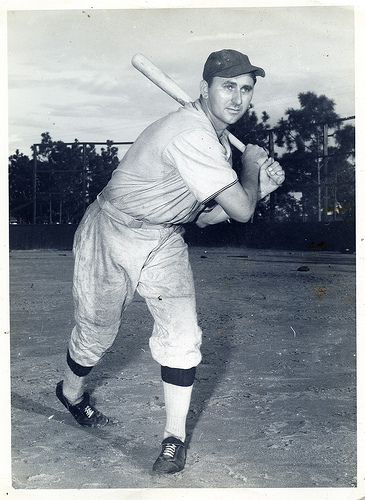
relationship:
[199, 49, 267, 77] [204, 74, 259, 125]
hat on head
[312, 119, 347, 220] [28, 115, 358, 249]
trees beyond fence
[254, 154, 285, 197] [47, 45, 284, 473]
hand of a person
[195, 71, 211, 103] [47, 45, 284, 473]
ear of a person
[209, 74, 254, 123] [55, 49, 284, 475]
face on man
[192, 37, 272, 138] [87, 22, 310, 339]
head on person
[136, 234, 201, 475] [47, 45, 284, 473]
leg on person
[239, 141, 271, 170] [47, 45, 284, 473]
hand on person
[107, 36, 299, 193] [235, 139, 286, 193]
bat in hands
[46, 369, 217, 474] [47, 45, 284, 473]
feet of person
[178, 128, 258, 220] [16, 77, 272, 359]
arm of person